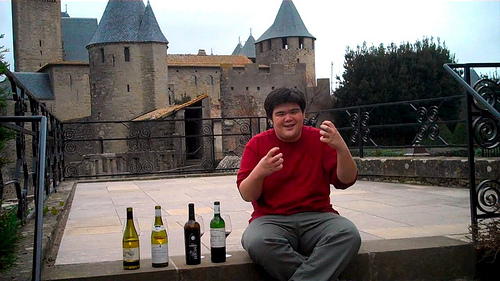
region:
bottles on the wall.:
[116, 196, 232, 271]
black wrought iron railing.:
[1, 60, 498, 269]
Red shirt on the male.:
[233, 88, 354, 235]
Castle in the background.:
[1, 2, 341, 172]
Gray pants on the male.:
[233, 81, 362, 279]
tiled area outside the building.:
[58, 168, 489, 279]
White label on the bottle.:
[148, 240, 174, 263]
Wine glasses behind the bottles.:
[187, 211, 237, 263]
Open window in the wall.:
[120, 45, 133, 68]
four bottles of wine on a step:
[122, 200, 227, 270]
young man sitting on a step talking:
[242, 88, 362, 278]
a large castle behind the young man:
[0, 3, 333, 142]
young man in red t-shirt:
[239, 90, 361, 280]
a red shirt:
[235, 125, 357, 215]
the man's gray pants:
[248, 213, 357, 280]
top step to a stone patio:
[42, 234, 472, 279]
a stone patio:
[51, 169, 498, 264]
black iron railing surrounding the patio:
[0, 63, 498, 246]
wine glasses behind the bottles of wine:
[121, 217, 232, 257]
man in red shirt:
[239, 136, 350, 210]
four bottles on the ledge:
[108, 209, 231, 278]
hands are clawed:
[263, 129, 350, 164]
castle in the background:
[16, 15, 237, 167]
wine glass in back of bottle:
[223, 220, 235, 236]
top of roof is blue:
[253, 0, 329, 42]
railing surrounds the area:
[58, 115, 243, 173]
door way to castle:
[181, 94, 206, 181]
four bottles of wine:
[115, 199, 225, 263]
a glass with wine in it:
[216, 215, 232, 257]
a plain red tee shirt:
[237, 124, 354, 214]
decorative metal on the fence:
[472, 78, 498, 148]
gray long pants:
[242, 214, 361, 275]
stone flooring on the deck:
[57, 174, 479, 252]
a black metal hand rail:
[30, 116, 46, 278]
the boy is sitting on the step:
[237, 86, 361, 278]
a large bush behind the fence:
[333, 38, 458, 145]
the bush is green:
[0, 202, 22, 272]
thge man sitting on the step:
[237, 80, 374, 280]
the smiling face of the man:
[259, 83, 313, 140]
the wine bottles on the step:
[116, 202, 227, 268]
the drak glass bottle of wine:
[183, 202, 201, 266]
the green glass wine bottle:
[207, 199, 227, 266]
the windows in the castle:
[96, 43, 137, 71]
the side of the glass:
[222, 208, 230, 237]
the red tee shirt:
[232, 122, 352, 214]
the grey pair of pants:
[239, 209, 362, 279]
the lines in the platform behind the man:
[347, 188, 467, 220]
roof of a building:
[86, 0, 166, 57]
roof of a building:
[258, 8, 313, 39]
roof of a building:
[242, 28, 262, 64]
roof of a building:
[232, 33, 245, 63]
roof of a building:
[208, 49, 217, 58]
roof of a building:
[9, 63, 49, 102]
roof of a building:
[50, 8, 90, 75]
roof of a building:
[161, 51, 244, 66]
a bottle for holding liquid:
[121, 207, 143, 267]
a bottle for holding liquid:
[143, 202, 168, 267]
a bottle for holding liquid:
[183, 202, 204, 259]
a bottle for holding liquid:
[211, 198, 228, 258]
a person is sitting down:
[241, 90, 365, 279]